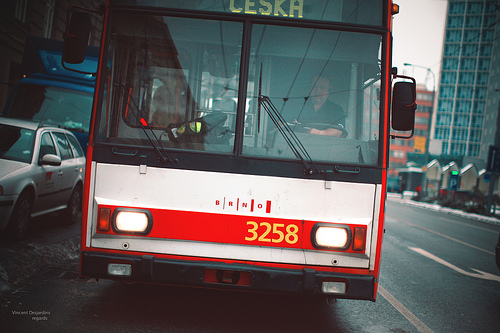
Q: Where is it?
A: This is at the street.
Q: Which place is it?
A: It is a street.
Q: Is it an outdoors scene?
A: Yes, it is outdoors.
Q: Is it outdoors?
A: Yes, it is outdoors.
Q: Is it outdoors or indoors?
A: It is outdoors.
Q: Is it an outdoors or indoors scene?
A: It is outdoors.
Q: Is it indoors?
A: No, it is outdoors.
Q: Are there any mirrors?
A: Yes, there is a mirror.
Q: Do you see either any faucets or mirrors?
A: Yes, there is a mirror.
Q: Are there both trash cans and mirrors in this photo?
A: No, there is a mirror but no trash cans.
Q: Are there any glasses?
A: No, there are no glasses.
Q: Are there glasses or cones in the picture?
A: No, there are no glasses or cones.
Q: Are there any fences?
A: No, there are no fences.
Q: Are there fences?
A: No, there are no fences.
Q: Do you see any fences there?
A: No, there are no fences.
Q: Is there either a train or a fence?
A: No, there are no fences or trains.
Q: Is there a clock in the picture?
A: No, there are no clocks.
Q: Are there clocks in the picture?
A: No, there are no clocks.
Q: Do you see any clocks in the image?
A: No, there are no clocks.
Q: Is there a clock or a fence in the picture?
A: No, there are no clocks or fences.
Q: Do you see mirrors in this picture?
A: Yes, there is a mirror.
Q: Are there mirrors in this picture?
A: Yes, there is a mirror.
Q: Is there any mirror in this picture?
A: Yes, there is a mirror.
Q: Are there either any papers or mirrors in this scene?
A: Yes, there is a mirror.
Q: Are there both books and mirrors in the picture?
A: No, there is a mirror but no books.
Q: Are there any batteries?
A: No, there are no batteries.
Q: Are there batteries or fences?
A: No, there are no batteries or fences.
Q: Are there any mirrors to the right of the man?
A: Yes, there is a mirror to the right of the man.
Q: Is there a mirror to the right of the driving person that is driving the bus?
A: Yes, there is a mirror to the right of the man.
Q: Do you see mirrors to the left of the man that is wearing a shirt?
A: No, the mirror is to the right of the man.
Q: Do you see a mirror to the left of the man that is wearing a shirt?
A: No, the mirror is to the right of the man.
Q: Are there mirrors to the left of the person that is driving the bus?
A: No, the mirror is to the right of the man.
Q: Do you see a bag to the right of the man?
A: No, there is a mirror to the right of the man.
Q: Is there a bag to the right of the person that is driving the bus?
A: No, there is a mirror to the right of the man.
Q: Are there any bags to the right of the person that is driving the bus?
A: No, there is a mirror to the right of the man.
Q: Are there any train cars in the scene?
A: No, there are no train cars.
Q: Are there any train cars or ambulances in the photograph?
A: No, there are no train cars or ambulances.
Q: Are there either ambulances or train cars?
A: No, there are no train cars or ambulances.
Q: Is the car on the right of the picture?
A: No, the car is on the left of the image.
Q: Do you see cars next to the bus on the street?
A: Yes, there is a car next to the bus.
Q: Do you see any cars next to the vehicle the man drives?
A: Yes, there is a car next to the bus.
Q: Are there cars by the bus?
A: Yes, there is a car by the bus.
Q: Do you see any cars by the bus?
A: Yes, there is a car by the bus.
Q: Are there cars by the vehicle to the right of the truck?
A: Yes, there is a car by the bus.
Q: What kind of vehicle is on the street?
A: The vehicle is a car.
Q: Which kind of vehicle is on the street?
A: The vehicle is a car.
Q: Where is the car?
A: The car is on the street.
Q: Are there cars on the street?
A: Yes, there is a car on the street.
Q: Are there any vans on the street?
A: No, there is a car on the street.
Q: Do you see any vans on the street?
A: No, there is a car on the street.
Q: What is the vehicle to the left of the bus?
A: The vehicle is a car.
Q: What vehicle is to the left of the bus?
A: The vehicle is a car.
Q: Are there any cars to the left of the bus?
A: Yes, there is a car to the left of the bus.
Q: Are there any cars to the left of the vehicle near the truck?
A: Yes, there is a car to the left of the bus.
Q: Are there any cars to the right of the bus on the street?
A: No, the car is to the left of the bus.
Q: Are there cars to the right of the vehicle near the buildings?
A: No, the car is to the left of the bus.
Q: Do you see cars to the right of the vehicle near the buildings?
A: No, the car is to the left of the bus.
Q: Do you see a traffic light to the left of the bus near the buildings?
A: No, there is a car to the left of the bus.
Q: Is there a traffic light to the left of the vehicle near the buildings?
A: No, there is a car to the left of the bus.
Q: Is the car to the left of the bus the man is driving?
A: Yes, the car is to the left of the bus.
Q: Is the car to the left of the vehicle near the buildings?
A: Yes, the car is to the left of the bus.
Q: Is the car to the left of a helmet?
A: No, the car is to the left of the bus.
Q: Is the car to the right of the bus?
A: No, the car is to the left of the bus.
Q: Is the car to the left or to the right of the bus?
A: The car is to the left of the bus.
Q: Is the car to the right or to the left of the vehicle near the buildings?
A: The car is to the left of the bus.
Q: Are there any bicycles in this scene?
A: No, there are no bicycles.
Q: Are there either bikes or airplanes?
A: No, there are no bikes or airplanes.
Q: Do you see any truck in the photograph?
A: Yes, there is a truck.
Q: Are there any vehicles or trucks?
A: Yes, there is a truck.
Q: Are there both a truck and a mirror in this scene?
A: Yes, there are both a truck and a mirror.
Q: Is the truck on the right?
A: No, the truck is on the left of the image.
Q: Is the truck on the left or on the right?
A: The truck is on the left of the image.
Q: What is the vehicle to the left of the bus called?
A: The vehicle is a truck.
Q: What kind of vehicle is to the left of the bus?
A: The vehicle is a truck.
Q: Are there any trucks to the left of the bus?
A: Yes, there is a truck to the left of the bus.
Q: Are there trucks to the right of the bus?
A: No, the truck is to the left of the bus.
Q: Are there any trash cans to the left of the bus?
A: No, there is a truck to the left of the bus.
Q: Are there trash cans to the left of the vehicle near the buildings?
A: No, there is a truck to the left of the bus.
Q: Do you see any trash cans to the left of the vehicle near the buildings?
A: No, there is a truck to the left of the bus.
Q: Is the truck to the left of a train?
A: No, the truck is to the left of the bus.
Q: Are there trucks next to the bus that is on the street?
A: Yes, there is a truck next to the bus.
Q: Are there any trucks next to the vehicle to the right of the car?
A: Yes, there is a truck next to the bus.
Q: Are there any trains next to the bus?
A: No, there is a truck next to the bus.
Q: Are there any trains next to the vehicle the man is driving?
A: No, there is a truck next to the bus.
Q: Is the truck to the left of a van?
A: No, the truck is to the left of a mirror.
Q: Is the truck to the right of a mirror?
A: No, the truck is to the left of a mirror.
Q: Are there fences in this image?
A: No, there are no fences.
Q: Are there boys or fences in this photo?
A: No, there are no fences or boys.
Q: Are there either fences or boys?
A: No, there are no fences or boys.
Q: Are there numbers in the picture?
A: Yes, there are numbers.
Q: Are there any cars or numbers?
A: Yes, there are numbers.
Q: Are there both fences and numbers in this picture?
A: No, there are numbers but no fences.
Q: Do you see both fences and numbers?
A: No, there are numbers but no fences.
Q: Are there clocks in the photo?
A: No, there are no clocks.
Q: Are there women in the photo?
A: No, there are no women.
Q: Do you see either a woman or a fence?
A: No, there are no women or fences.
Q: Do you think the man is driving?
A: Yes, the man is driving.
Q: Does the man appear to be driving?
A: Yes, the man is driving.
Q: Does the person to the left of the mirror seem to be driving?
A: Yes, the man is driving.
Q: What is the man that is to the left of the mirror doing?
A: The man is driving.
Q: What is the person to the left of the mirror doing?
A: The man is driving.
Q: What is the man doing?
A: The man is driving.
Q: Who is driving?
A: The man is driving.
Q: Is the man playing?
A: No, the man is driving.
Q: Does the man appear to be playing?
A: No, the man is driving.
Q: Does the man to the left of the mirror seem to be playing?
A: No, the man is driving.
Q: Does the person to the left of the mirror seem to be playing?
A: No, the man is driving.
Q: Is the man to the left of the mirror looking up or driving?
A: The man is driving.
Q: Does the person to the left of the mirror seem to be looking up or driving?
A: The man is driving.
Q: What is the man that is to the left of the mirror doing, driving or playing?
A: The man is driving.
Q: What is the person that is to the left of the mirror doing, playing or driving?
A: The man is driving.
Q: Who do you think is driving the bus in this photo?
A: The man is driving the bus.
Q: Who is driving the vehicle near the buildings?
A: The man is driving the bus.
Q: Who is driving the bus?
A: The man is driving the bus.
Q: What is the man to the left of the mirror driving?
A: The man is driving the bus.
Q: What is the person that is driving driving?
A: The man is driving the bus.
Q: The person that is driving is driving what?
A: The man is driving the bus.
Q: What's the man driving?
A: The man is driving the bus.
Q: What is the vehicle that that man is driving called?
A: The vehicle is a bus.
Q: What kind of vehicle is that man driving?
A: The man is driving the bus.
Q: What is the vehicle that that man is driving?
A: The vehicle is a bus.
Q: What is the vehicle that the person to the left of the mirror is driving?
A: The vehicle is a bus.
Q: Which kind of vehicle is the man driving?
A: The man is driving the bus.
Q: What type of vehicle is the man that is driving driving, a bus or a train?
A: The man is driving a bus.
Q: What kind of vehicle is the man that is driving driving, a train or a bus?
A: The man is driving a bus.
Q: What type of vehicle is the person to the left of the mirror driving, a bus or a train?
A: The man is driving a bus.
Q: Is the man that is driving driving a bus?
A: Yes, the man is driving a bus.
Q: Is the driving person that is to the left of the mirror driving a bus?
A: Yes, the man is driving a bus.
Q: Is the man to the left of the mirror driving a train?
A: No, the man is driving a bus.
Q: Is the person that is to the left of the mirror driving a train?
A: No, the man is driving a bus.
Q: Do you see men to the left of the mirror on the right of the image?
A: Yes, there is a man to the left of the mirror.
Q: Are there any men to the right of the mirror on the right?
A: No, the man is to the left of the mirror.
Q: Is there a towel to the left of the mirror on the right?
A: No, there is a man to the left of the mirror.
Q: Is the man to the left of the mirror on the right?
A: Yes, the man is to the left of the mirror.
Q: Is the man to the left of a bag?
A: No, the man is to the left of the mirror.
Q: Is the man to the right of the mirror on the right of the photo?
A: No, the man is to the left of the mirror.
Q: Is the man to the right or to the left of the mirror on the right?
A: The man is to the left of the mirror.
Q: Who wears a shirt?
A: The man wears a shirt.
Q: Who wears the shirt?
A: The man wears a shirt.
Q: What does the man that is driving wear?
A: The man wears a shirt.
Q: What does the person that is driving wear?
A: The man wears a shirt.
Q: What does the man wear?
A: The man wears a shirt.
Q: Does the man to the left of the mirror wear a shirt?
A: Yes, the man wears a shirt.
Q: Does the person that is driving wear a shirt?
A: Yes, the man wears a shirt.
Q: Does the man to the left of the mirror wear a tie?
A: No, the man wears a shirt.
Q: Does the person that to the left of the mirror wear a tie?
A: No, the man wears a shirt.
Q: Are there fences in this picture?
A: No, there are no fences.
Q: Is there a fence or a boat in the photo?
A: No, there are no fences or boats.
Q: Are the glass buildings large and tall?
A: Yes, the buildings are large and tall.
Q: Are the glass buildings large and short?
A: No, the buildings are large but tall.